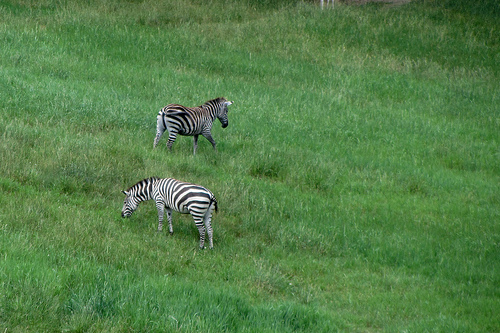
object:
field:
[0, 0, 498, 331]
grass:
[65, 278, 159, 332]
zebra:
[121, 176, 222, 251]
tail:
[212, 196, 219, 215]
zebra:
[149, 96, 233, 156]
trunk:
[317, 0, 328, 12]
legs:
[152, 128, 165, 151]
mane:
[126, 175, 161, 192]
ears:
[120, 189, 130, 197]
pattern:
[191, 113, 207, 127]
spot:
[168, 212, 172, 216]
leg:
[165, 207, 174, 237]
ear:
[226, 99, 234, 107]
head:
[118, 188, 139, 219]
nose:
[121, 210, 125, 219]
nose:
[225, 122, 230, 127]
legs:
[154, 201, 166, 232]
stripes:
[161, 178, 168, 195]